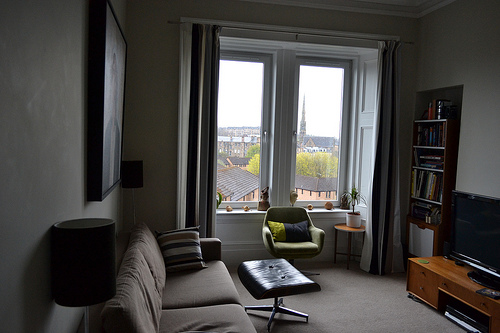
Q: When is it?
A: Day time.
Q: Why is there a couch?
A: It is a living room.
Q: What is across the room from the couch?
A: A tv.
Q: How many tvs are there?
A: 1.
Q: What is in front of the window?
A: A chair.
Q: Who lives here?
A: A person.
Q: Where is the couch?
A: Across from the tv.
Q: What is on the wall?
A: A picture.